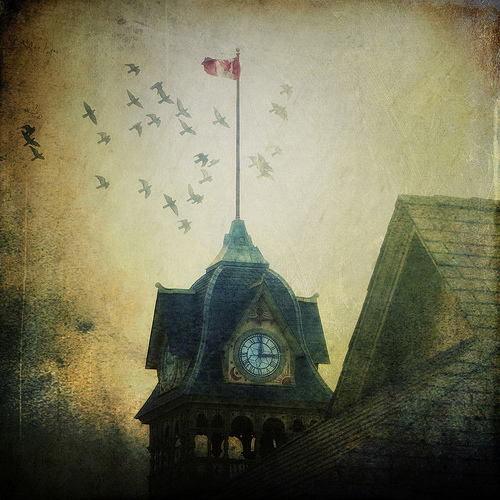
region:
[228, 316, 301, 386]
This a big clock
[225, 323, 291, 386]
This a very big clock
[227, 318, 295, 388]
This a white clock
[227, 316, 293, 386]
This a big clock showing 3pm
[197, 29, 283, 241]
This is a flag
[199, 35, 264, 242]
This is a red and white flag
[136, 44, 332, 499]
This is a high tower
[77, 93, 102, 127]
This is a bird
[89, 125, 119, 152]
This is a bird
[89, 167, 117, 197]
This is a bird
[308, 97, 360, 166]
part of the sky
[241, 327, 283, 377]
part of a clock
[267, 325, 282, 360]
edge of a clock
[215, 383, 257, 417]
part of a tower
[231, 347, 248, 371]
edge of a clock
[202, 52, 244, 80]
the flag at the end of the pole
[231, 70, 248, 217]
the flag pole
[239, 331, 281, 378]
the white round clock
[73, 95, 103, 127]
the bird in the sky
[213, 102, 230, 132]
the bird in the sky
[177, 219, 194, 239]
the bird in the sky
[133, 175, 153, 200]
the bird in the sky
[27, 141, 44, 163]
the bird in the sky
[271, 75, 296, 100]
the bird in the sky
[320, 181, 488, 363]
the triangle roof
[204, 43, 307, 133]
Red and white flag on top of pole.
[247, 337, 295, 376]
Black hands on clock.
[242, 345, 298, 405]
White face on clock.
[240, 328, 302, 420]
Black numbers on clock.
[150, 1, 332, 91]
the flag is waving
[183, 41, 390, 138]
the flag is waving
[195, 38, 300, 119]
the flag is waving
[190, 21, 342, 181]
the flag is waving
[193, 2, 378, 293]
the flag is waving